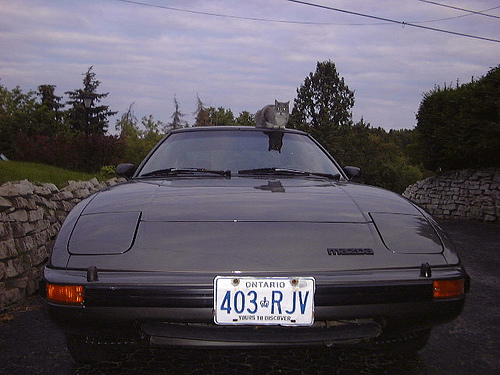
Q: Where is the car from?
A: Ontario.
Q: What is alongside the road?
A: Stone walls.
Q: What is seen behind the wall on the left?
A: Grass.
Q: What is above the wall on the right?
A: Green shrubbery.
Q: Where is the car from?
A: Canada.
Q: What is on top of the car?
A: Cat.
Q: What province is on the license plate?
A: Ontario.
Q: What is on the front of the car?
A: License plate.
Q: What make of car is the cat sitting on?
A: Mazda.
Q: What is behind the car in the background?
A: Trees.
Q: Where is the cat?
A: On top of the car.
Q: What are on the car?
A: Ontario plates.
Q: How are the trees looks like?
A: Tall.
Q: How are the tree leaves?
A: Green.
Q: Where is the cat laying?
A: On roof of car.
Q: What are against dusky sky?
A: Conifer trees.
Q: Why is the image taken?
A: Remembrance.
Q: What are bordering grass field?
A: Line of green trees.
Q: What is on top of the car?
A: A cat.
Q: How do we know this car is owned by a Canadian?
A: It has an Ontario license plate.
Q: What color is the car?
A: Black.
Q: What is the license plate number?
A: 403 RJV.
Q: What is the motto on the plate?
A: Yours to Discover.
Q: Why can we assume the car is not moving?
A: Because it has a cat on it.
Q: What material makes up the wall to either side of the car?
A: Stones.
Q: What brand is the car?
A: A Mazda.